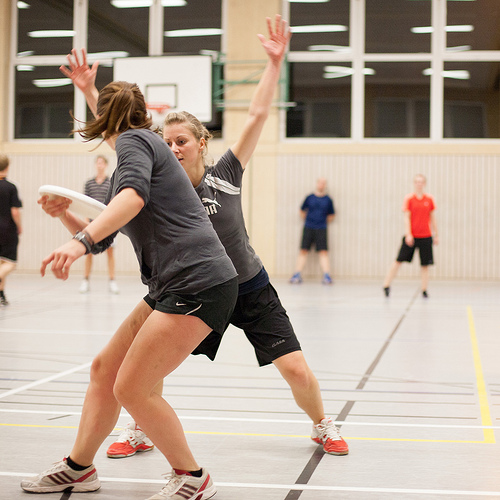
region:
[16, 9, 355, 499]
the two girls playing frisbee on the court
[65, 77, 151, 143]
the girl's brown hair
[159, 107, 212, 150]
the girl's blond hair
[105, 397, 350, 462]
the girl's red shoes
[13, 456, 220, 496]
the girl's light colored shoes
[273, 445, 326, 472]
the black lines on the court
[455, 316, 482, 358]
the yellow lines on the court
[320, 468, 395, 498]
the white lines on the court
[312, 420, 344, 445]
the white shoe laces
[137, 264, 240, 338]
the short black shorts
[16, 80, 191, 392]
a woman playing frisbee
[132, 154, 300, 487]
a woman playing frisbee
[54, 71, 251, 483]
a woman playing frisbee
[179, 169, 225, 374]
a woman playing frisbee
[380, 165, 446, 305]
A girl n red playing a game.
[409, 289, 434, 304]
a black shoe.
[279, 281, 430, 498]
a line going through a court.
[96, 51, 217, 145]
a large basketball hoop.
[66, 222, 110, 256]
a black wrist watch.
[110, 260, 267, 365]
a pair of black shorts.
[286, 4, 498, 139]
a large gymnasium window.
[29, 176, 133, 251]
a white frisbee.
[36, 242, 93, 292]
left hand.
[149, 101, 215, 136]
hair on a girl's head.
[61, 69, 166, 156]
the head of a girl.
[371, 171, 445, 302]
a kid wearing a red shirt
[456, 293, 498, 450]
a yellow line painted on a floor.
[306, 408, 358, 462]
a left red shoe.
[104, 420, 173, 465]
a right red shoe.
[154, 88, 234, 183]
a young girl.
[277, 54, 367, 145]
a window in a gym.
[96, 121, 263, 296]
a dark gray t shirt.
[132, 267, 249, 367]
a pair of short black shorts.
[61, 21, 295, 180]
the woman's arms are extended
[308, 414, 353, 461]
the woman is wearing red sneakers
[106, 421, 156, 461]
the woman is wearing red sneakers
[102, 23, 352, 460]
the player is a female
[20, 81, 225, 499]
the player is a female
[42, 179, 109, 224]
the woman is holding a frisbee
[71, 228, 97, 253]
the woman is wearinga wrist band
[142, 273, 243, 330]
the woman is wearing black shorts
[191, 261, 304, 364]
the woman is wearing black shorts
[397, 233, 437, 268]
the woman is wearing black shorts